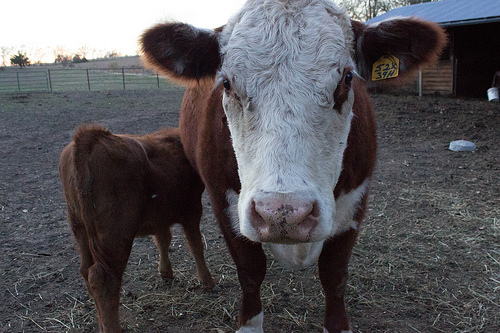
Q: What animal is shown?
A: Cows.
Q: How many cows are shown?
A: Two.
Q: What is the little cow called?
A: Calf.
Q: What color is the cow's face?
A: White.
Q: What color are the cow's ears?
A: Brown.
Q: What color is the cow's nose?
A: Pink.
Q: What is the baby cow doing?
A: Standing beside the adult cow.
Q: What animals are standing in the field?
A: Cows.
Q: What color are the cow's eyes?
A: Black.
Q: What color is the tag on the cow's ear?
A: Yellow.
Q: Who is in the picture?
A: Cows.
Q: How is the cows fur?
A: Coarse.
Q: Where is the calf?
A: Behind the cow.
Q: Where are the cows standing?
A: On grass.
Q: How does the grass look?
A: Dead.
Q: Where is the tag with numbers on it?
A: Cows ear.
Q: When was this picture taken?
A: Early morning.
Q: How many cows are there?
A: 2.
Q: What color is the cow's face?
A: White.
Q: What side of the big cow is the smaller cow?
A: Left.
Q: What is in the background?
A: Shed.